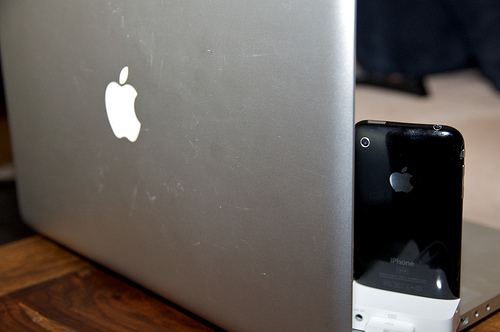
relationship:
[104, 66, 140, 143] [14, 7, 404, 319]
apple logo on computer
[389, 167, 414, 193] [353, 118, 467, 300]
apple image back cell phone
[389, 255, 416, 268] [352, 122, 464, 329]
writing on phone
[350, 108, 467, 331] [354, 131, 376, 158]
cell phone has camera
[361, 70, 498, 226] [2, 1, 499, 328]
flooring in room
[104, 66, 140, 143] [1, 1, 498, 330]
apple logo on computer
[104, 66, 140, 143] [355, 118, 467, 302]
apple logo on cellphone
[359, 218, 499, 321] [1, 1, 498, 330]
base of computer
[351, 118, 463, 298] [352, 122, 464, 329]
reflections on phone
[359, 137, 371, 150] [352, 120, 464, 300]
camera on phone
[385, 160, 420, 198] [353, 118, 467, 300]
apple image on cell phone